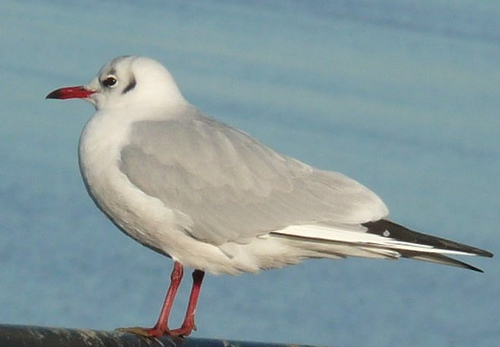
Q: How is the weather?
A: It is cloudy.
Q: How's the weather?
A: It is cloudy.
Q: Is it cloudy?
A: Yes, it is cloudy.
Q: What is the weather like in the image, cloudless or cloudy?
A: It is cloudy.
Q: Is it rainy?
A: No, it is cloudy.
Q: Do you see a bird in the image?
A: Yes, there is a bird.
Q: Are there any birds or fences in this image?
A: Yes, there is a bird.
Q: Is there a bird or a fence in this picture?
A: Yes, there is a bird.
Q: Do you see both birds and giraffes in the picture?
A: No, there is a bird but no giraffes.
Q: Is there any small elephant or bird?
A: Yes, there is a small bird.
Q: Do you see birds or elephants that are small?
A: Yes, the bird is small.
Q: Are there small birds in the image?
A: Yes, there is a small bird.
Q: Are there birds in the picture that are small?
A: Yes, there is a bird that is small.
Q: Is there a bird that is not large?
A: Yes, there is a small bird.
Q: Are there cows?
A: No, there are no cows.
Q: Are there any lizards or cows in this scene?
A: No, there are no cows or lizards.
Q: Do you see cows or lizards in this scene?
A: No, there are no cows or lizards.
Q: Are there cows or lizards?
A: No, there are no cows or lizards.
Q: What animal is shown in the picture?
A: The animal is a bird.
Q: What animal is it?
A: The animal is a bird.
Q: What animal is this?
A: This is a bird.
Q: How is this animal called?
A: This is a bird.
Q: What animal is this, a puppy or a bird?
A: This is a bird.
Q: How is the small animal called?
A: The animal is a bird.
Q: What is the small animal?
A: The animal is a bird.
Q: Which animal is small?
A: The animal is a bird.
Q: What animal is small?
A: The animal is a bird.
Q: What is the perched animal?
A: The animal is a bird.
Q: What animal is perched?
A: The animal is a bird.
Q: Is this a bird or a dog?
A: This is a bird.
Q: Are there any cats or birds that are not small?
A: No, there is a bird but it is small.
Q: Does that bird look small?
A: Yes, the bird is small.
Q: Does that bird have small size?
A: Yes, the bird is small.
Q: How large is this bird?
A: The bird is small.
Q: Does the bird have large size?
A: No, the bird is small.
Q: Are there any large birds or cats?
A: No, there is a bird but it is small.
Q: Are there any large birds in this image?
A: No, there is a bird but it is small.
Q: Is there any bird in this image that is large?
A: No, there is a bird but it is small.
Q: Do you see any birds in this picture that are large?
A: No, there is a bird but it is small.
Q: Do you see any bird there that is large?
A: No, there is a bird but it is small.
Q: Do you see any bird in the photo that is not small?
A: No, there is a bird but it is small.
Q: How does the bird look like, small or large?
A: The bird is small.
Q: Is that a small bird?
A: Yes, that is a small bird.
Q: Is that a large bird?
A: No, that is a small bird.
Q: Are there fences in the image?
A: No, there are no fences.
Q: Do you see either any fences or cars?
A: No, there are no fences or cars.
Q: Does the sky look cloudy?
A: Yes, the sky is cloudy.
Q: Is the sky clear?
A: No, the sky is cloudy.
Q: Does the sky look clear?
A: No, the sky is cloudy.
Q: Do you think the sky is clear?
A: No, the sky is cloudy.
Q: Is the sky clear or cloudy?
A: The sky is cloudy.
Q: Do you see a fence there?
A: No, there are no fences.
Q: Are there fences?
A: No, there are no fences.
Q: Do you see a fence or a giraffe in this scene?
A: No, there are no fences or giraffes.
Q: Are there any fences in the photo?
A: No, there are no fences.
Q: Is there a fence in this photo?
A: No, there are no fences.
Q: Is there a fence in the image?
A: No, there are no fences.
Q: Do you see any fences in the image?
A: No, there are no fences.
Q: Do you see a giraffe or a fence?
A: No, there are no fences or giraffes.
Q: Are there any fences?
A: No, there are no fences.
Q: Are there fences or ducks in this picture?
A: No, there are no fences or ducks.